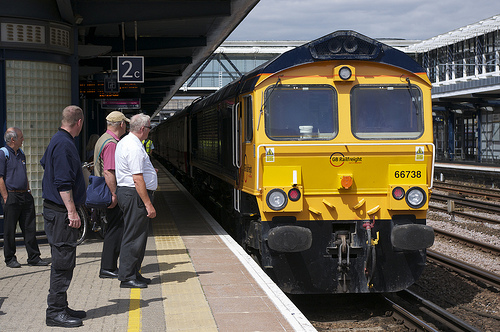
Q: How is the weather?
A: It is cloudy.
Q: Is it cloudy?
A: Yes, it is cloudy.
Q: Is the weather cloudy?
A: Yes, it is cloudy.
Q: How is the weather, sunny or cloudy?
A: It is cloudy.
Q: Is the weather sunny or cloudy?
A: It is cloudy.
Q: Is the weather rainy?
A: No, it is cloudy.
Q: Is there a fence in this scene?
A: No, there are no fences.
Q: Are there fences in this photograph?
A: No, there are no fences.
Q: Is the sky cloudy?
A: Yes, the sky is cloudy.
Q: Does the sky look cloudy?
A: Yes, the sky is cloudy.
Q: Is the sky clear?
A: No, the sky is cloudy.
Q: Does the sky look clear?
A: No, the sky is cloudy.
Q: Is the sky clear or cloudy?
A: The sky is cloudy.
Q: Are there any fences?
A: No, there are no fences.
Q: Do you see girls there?
A: No, there are no girls.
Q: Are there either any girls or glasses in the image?
A: No, there are no girls or glasses.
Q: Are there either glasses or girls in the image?
A: No, there are no girls or glasses.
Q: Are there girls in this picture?
A: No, there are no girls.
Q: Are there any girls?
A: No, there are no girls.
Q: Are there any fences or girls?
A: No, there are no girls or fences.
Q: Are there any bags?
A: Yes, there is a bag.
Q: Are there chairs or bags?
A: Yes, there is a bag.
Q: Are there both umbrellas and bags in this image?
A: No, there is a bag but no umbrellas.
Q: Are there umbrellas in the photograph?
A: No, there are no umbrellas.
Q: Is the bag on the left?
A: Yes, the bag is on the left of the image.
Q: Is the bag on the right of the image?
A: No, the bag is on the left of the image.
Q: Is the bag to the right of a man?
A: No, the bag is to the left of a man.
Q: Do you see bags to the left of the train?
A: Yes, there is a bag to the left of the train.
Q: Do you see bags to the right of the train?
A: No, the bag is to the left of the train.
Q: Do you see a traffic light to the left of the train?
A: No, there is a bag to the left of the train.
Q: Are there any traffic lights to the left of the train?
A: No, there is a bag to the left of the train.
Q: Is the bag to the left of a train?
A: Yes, the bag is to the left of a train.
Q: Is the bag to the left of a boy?
A: No, the bag is to the left of a train.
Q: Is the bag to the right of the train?
A: No, the bag is to the left of the train.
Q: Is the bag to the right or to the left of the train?
A: The bag is to the left of the train.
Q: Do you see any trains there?
A: Yes, there is a train.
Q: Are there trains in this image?
A: Yes, there is a train.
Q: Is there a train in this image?
A: Yes, there is a train.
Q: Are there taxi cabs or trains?
A: Yes, there is a train.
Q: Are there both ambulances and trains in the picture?
A: No, there is a train but no ambulances.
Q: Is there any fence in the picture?
A: No, there are no fences.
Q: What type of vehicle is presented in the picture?
A: The vehicle is a train.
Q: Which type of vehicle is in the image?
A: The vehicle is a train.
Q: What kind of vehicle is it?
A: The vehicle is a train.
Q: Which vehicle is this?
A: This is a train.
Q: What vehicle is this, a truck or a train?
A: This is a train.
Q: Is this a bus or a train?
A: This is a train.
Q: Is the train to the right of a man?
A: Yes, the train is to the right of a man.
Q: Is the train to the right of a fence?
A: No, the train is to the right of a man.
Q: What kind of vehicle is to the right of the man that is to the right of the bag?
A: The vehicle is a train.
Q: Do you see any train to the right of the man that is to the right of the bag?
A: Yes, there is a train to the right of the man.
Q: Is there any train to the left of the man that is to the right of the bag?
A: No, the train is to the right of the man.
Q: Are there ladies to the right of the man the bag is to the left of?
A: No, there is a train to the right of the man.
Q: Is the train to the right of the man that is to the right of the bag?
A: Yes, the train is to the right of the man.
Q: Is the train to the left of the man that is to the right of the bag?
A: No, the train is to the right of the man.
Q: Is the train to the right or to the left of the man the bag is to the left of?
A: The train is to the right of the man.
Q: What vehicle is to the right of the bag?
A: The vehicle is a train.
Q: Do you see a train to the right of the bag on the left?
A: Yes, there is a train to the right of the bag.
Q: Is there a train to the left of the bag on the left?
A: No, the train is to the right of the bag.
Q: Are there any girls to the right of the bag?
A: No, there is a train to the right of the bag.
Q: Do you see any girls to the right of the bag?
A: No, there is a train to the right of the bag.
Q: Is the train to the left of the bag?
A: No, the train is to the right of the bag.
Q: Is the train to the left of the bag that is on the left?
A: No, the train is to the right of the bag.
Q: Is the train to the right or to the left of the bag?
A: The train is to the right of the bag.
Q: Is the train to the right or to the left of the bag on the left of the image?
A: The train is to the right of the bag.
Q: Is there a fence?
A: No, there are no fences.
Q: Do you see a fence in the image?
A: No, there are no fences.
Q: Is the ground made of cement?
A: Yes, the ground is made of cement.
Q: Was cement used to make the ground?
A: Yes, the ground is made of cement.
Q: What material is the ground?
A: The ground is made of concrete.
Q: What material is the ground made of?
A: The ground is made of concrete.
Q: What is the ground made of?
A: The ground is made of concrete.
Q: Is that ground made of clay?
A: No, the ground is made of cement.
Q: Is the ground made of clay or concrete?
A: The ground is made of concrete.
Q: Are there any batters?
A: No, there are no batters.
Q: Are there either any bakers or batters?
A: No, there are no batters or bakers.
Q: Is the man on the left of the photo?
A: Yes, the man is on the left of the image.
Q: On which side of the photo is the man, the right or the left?
A: The man is on the left of the image.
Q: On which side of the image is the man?
A: The man is on the left of the image.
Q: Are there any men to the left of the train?
A: Yes, there is a man to the left of the train.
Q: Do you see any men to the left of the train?
A: Yes, there is a man to the left of the train.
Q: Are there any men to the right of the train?
A: No, the man is to the left of the train.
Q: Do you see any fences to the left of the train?
A: No, there is a man to the left of the train.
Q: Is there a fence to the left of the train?
A: No, there is a man to the left of the train.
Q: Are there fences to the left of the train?
A: No, there is a man to the left of the train.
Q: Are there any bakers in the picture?
A: No, there are no bakers.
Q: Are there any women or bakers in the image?
A: No, there are no bakers or women.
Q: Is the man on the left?
A: Yes, the man is on the left of the image.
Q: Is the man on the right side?
A: No, the man is on the left of the image.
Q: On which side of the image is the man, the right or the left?
A: The man is on the left of the image.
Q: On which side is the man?
A: The man is on the left of the image.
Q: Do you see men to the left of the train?
A: Yes, there is a man to the left of the train.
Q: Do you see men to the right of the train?
A: No, the man is to the left of the train.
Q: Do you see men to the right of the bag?
A: Yes, there is a man to the right of the bag.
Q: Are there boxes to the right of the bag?
A: No, there is a man to the right of the bag.